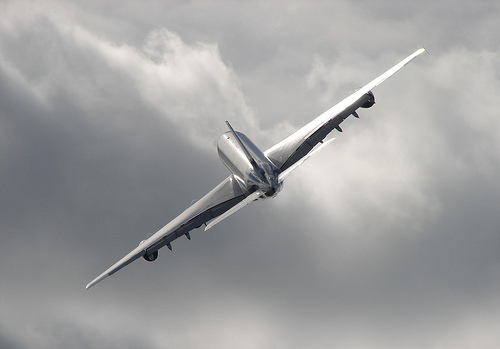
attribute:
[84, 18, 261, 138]
cloud — white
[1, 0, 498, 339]
clouds — thin, gray, white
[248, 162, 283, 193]
tail — silver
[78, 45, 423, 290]
wings — silver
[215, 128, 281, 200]
body — silver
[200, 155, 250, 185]
shadow — black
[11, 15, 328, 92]
sky — overcast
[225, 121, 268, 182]
tail — horizontal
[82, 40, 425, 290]
plane — silver, tilted, reflective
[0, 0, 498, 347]
sky — gray